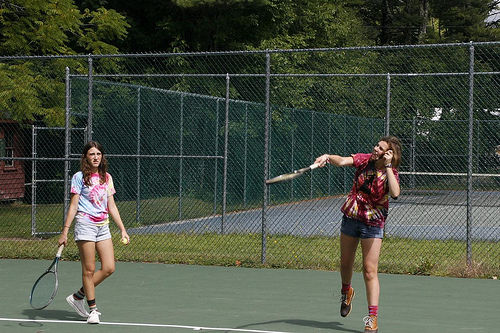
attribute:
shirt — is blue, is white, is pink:
[67, 165, 127, 250]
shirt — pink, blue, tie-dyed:
[58, 169, 132, 227]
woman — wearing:
[59, 140, 121, 322]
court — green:
[3, 252, 458, 331]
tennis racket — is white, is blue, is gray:
[28, 245, 64, 310]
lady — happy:
[273, 114, 415, 330]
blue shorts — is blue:
[338, 212, 385, 241]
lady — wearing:
[48, 118, 152, 331]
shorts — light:
[69, 214, 115, 242]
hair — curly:
[386, 135, 404, 173]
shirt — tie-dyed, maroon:
[338, 151, 398, 225]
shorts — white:
[68, 212, 115, 252]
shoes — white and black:
[53, 290, 106, 330]